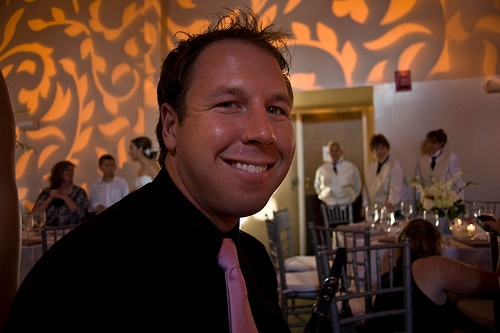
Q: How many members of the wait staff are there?
A: Three.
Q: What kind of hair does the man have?
A: Spiked.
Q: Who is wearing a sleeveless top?
A: A woman.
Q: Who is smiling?
A: A man.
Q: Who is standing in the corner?
A: Server.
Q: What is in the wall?
A: Lighted decorations.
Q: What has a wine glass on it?
A: Table.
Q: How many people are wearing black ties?
A: 3.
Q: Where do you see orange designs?
A: On the walls.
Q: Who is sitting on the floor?
A: A woman.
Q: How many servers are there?
A: 3.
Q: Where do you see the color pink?
A: On the man's tie.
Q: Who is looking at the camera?
A: Man with pink tie.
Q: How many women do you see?
A: 3.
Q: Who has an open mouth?
A: Man with pink tie.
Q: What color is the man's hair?
A: Black.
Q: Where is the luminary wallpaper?
A: On the wall.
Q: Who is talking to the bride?
A: The people.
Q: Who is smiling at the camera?
A: The man.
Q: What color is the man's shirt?
A: The man's shirt is black.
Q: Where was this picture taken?
A: The picture looks like it was taken in a restaurant.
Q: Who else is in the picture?
A: There are 7 other people in the picture.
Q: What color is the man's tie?
A: The mans tie is pink.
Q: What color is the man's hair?
A: The mans hair is brown.